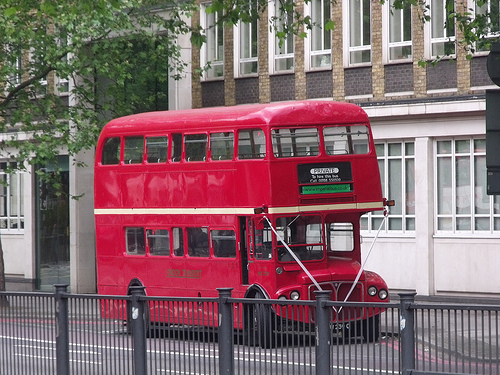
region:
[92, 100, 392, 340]
a 2 story red bus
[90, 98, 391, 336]
english city bus on the road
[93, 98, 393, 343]
a red double decker bus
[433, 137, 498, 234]
a gray window with white panes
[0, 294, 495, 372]
a grey metal fence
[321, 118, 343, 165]
a window on a bus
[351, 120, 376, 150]
a window on a bus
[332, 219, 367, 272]
a window on a bus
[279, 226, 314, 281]
a window on a bus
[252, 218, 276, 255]
a window on a bus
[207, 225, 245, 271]
a window on a bus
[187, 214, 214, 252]
a window on a bus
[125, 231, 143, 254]
a window on a bus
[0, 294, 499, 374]
gray steel railed fence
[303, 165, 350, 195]
sign on front of bus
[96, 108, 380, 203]
upper tier of double decker bus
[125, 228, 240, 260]
windows on lower tier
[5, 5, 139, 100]
leaves on the branches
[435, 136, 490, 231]
white window on building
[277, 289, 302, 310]
lights on front of bus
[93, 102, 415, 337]
red double decker bus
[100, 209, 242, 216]
white line on bus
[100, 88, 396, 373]
a bus on the road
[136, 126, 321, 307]
a bus on the street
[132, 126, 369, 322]
a red bus on the road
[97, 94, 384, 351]
a passenger bus on teh treet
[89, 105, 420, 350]
a double decker bus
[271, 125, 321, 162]
a window on a bus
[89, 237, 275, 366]
a tall metal fence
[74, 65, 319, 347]
red double decker bus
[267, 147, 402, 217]
white and green ad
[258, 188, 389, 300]
white poles on bus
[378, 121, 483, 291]
white wall behind bus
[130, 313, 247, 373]
white lines on road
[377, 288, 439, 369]
road is dark grey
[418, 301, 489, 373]
sidewalk is light grey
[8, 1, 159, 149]
green tree near bus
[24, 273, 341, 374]
black fence in front of bus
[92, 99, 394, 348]
Large red bus on the street.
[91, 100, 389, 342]
Bus with two levels.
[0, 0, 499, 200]
Tree leaves above the street.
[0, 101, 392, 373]
A bus is parked on the street.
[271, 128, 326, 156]
front window of the bus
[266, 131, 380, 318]
frontal red and black bus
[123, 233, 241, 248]
right side of the bus windows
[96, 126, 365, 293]
Red bus on the pavement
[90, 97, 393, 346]
red bus is parked on street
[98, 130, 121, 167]
window belongs to bus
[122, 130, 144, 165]
window belongs to bus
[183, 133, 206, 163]
window belongs to bus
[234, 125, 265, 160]
window belongs to bus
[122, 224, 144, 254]
window belongs to bus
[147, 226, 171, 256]
window belongs to bus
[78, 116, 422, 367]
a bus that is red and white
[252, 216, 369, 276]
the front window of a red bus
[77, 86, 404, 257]
the second story of a red bus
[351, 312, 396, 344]
the front right wheel of a red bus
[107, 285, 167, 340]
the back wheel of a red bus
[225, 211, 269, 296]
the door of a red bus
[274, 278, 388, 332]
the front lights of a red bus